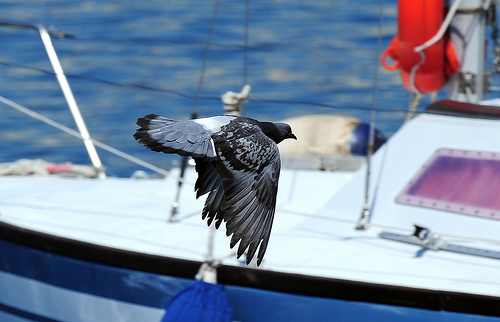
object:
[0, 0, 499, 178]
water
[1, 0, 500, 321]
boat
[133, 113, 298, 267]
bird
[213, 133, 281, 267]
wing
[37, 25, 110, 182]
metal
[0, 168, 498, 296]
deck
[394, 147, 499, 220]
window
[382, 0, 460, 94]
floatation device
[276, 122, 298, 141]
head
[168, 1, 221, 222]
ropes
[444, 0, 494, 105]
pole